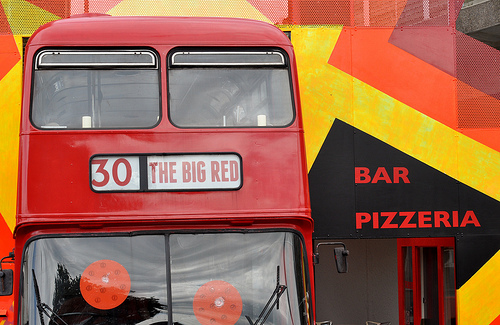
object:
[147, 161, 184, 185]
words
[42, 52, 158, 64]
window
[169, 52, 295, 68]
window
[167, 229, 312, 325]
windshield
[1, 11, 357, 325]
bus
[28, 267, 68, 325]
wipers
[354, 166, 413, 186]
word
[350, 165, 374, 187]
letters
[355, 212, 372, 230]
letters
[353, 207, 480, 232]
word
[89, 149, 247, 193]
sign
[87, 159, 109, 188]
numbers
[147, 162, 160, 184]
letters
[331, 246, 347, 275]
mirror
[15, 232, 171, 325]
windows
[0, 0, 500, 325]
building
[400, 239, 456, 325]
door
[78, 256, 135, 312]
circles